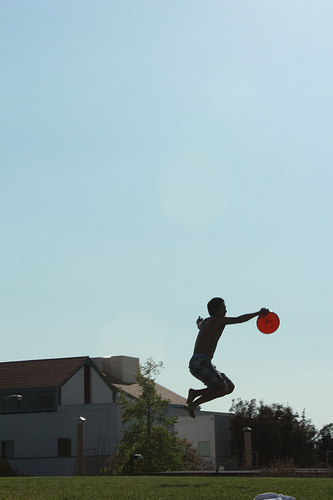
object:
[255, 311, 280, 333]
frisbee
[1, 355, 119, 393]
roof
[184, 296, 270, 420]
man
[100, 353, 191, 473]
tree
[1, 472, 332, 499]
grass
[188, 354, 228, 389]
shorts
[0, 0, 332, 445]
sky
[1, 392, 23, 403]
street light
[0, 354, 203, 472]
building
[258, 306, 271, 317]
hand